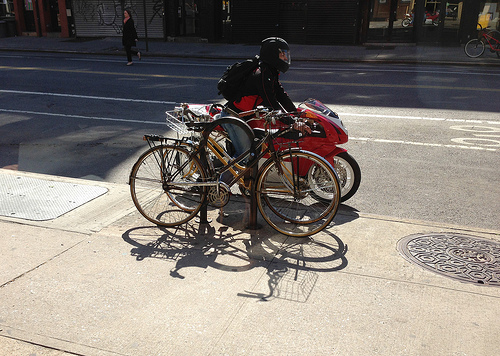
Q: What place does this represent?
A: It represents the city.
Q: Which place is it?
A: It is a city.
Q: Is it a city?
A: Yes, it is a city.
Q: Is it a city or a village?
A: It is a city.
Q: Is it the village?
A: No, it is the city.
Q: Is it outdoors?
A: Yes, it is outdoors.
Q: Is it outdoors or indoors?
A: It is outdoors.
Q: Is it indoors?
A: No, it is outdoors.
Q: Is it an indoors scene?
A: No, it is outdoors.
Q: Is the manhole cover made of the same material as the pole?
A: Yes, both the manhole cover and the pole are made of metal.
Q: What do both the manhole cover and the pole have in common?
A: The material, both the manhole cover and the pole are metallic.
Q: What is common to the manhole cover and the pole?
A: The material, both the manhole cover and the pole are metallic.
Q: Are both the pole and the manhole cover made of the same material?
A: Yes, both the pole and the manhole cover are made of metal.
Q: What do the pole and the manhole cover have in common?
A: The material, both the pole and the manhole cover are metallic.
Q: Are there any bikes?
A: Yes, there is a bike.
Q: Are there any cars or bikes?
A: Yes, there is a bike.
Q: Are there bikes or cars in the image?
A: Yes, there is a bike.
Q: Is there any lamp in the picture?
A: No, there are no lamps.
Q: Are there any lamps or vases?
A: No, there are no lamps or vases.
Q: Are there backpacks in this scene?
A: Yes, there is a backpack.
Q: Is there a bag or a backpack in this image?
A: Yes, there is a backpack.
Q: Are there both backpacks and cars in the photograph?
A: No, there is a backpack but no cars.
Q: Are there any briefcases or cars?
A: No, there are no cars or briefcases.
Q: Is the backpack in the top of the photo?
A: Yes, the backpack is in the top of the image.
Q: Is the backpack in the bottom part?
A: No, the backpack is in the top of the image.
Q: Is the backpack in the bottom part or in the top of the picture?
A: The backpack is in the top of the image.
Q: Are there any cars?
A: No, there are no cars.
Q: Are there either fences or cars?
A: No, there are no cars or fences.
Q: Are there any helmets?
A: Yes, there is a helmet.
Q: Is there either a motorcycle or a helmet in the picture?
A: Yes, there is a helmet.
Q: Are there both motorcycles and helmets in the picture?
A: Yes, there are both a helmet and a motorcycle.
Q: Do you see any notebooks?
A: No, there are no notebooks.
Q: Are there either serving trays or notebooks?
A: No, there are no notebooks or serving trays.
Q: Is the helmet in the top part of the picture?
A: Yes, the helmet is in the top of the image.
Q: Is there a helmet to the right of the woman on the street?
A: Yes, there is a helmet to the right of the woman.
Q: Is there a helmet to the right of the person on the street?
A: Yes, there is a helmet to the right of the woman.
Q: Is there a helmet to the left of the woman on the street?
A: No, the helmet is to the right of the woman.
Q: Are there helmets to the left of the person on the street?
A: No, the helmet is to the right of the woman.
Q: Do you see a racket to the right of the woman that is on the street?
A: No, there is a helmet to the right of the woman.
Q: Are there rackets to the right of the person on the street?
A: No, there is a helmet to the right of the woman.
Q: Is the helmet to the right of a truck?
A: No, the helmet is to the right of the woman.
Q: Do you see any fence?
A: No, there are no fences.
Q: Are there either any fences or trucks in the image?
A: No, there are no fences or trucks.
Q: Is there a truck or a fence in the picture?
A: No, there are no fences or trucks.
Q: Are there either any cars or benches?
A: No, there are no cars or benches.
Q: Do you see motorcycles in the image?
A: Yes, there is a motorcycle.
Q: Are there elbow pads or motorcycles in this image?
A: Yes, there is a motorcycle.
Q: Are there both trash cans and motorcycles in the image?
A: No, there is a motorcycle but no trash cans.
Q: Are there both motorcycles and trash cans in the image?
A: No, there is a motorcycle but no trash cans.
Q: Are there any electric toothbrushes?
A: No, there are no electric toothbrushes.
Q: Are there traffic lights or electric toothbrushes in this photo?
A: No, there are no electric toothbrushes or traffic lights.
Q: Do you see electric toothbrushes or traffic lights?
A: No, there are no electric toothbrushes or traffic lights.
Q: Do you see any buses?
A: No, there are no buses.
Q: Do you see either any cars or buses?
A: No, there are no buses or cars.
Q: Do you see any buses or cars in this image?
A: No, there are no buses or cars.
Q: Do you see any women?
A: Yes, there is a woman.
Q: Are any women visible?
A: Yes, there is a woman.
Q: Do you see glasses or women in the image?
A: Yes, there is a woman.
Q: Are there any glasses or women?
A: Yes, there is a woman.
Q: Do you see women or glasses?
A: Yes, there is a woman.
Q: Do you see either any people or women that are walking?
A: Yes, the woman is walking.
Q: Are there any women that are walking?
A: Yes, there is a woman that is walking.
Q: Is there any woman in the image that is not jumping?
A: Yes, there is a woman that is walking.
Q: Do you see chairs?
A: No, there are no chairs.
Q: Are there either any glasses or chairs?
A: No, there are no chairs or glasses.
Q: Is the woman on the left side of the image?
A: Yes, the woman is on the left of the image.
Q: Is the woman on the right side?
A: No, the woman is on the left of the image.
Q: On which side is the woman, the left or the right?
A: The woman is on the left of the image.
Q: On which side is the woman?
A: The woman is on the left of the image.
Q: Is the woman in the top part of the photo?
A: Yes, the woman is in the top of the image.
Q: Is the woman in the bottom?
A: No, the woman is in the top of the image.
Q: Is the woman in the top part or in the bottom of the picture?
A: The woman is in the top of the image.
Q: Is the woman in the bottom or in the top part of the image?
A: The woman is in the top of the image.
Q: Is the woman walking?
A: Yes, the woman is walking.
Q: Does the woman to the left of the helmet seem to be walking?
A: Yes, the woman is walking.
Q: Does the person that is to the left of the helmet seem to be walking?
A: Yes, the woman is walking.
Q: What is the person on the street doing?
A: The woman is walking.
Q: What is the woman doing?
A: The woman is walking.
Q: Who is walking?
A: The woman is walking.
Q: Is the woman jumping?
A: No, the woman is walking.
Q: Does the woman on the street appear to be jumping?
A: No, the woman is walking.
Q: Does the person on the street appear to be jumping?
A: No, the woman is walking.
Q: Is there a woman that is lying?
A: No, there is a woman but she is walking.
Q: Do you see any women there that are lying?
A: No, there is a woman but she is walking.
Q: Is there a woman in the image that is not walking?
A: No, there is a woman but she is walking.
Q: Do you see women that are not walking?
A: No, there is a woman but she is walking.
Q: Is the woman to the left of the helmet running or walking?
A: The woman is walking.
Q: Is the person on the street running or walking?
A: The woman is walking.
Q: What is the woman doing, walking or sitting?
A: The woman is walking.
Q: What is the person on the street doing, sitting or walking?
A: The woman is walking.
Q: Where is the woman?
A: The woman is on the street.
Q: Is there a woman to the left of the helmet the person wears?
A: Yes, there is a woman to the left of the helmet.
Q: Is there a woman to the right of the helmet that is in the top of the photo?
A: No, the woman is to the left of the helmet.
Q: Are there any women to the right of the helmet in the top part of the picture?
A: No, the woman is to the left of the helmet.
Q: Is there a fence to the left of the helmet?
A: No, there is a woman to the left of the helmet.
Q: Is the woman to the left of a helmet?
A: Yes, the woman is to the left of a helmet.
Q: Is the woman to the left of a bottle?
A: No, the woman is to the left of a helmet.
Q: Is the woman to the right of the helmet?
A: No, the woman is to the left of the helmet.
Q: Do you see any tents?
A: No, there are no tents.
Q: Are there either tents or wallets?
A: No, there are no tents or wallets.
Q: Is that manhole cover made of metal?
A: Yes, the manhole cover is made of metal.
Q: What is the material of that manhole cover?
A: The manhole cover is made of metal.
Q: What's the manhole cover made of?
A: The manhole cover is made of metal.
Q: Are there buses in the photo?
A: No, there are no buses.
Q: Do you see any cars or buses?
A: No, there are no buses or cars.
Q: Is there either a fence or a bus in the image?
A: No, there are no fences or buses.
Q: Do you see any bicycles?
A: Yes, there is a bicycle.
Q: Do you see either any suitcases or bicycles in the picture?
A: Yes, there is a bicycle.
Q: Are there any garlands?
A: No, there are no garlands.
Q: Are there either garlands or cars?
A: No, there are no garlands or cars.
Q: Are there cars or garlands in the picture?
A: No, there are no garlands or cars.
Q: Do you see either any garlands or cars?
A: No, there are no garlands or cars.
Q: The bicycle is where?
A: The bicycle is on the sidewalk.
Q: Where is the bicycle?
A: The bicycle is on the sidewalk.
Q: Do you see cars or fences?
A: No, there are no cars or fences.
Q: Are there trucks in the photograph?
A: No, there are no trucks.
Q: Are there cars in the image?
A: No, there are no cars.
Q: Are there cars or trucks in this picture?
A: No, there are no cars or trucks.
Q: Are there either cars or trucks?
A: No, there are no cars or trucks.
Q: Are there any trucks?
A: No, there are no trucks.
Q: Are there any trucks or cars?
A: No, there are no trucks or cars.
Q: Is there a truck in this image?
A: No, there are no trucks.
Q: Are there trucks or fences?
A: No, there are no trucks or fences.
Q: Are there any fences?
A: No, there are no fences.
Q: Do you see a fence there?
A: No, there are no fences.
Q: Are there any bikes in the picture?
A: Yes, there are bikes.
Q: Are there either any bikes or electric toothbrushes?
A: Yes, there are bikes.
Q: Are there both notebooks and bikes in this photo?
A: No, there are bikes but no notebooks.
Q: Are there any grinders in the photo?
A: No, there are no grinders.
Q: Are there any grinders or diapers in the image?
A: No, there are no grinders or diapers.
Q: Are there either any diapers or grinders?
A: No, there are no grinders or diapers.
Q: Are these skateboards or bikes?
A: These are bikes.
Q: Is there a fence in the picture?
A: No, there are no fences.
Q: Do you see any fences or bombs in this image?
A: No, there are no fences or bombs.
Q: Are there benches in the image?
A: No, there are no benches.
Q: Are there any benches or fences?
A: No, there are no benches or fences.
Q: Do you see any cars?
A: No, there are no cars.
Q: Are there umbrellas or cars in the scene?
A: No, there are no cars or umbrellas.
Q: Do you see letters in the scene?
A: Yes, there are letters.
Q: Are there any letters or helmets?
A: Yes, there are letters.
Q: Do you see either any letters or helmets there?
A: Yes, there are letters.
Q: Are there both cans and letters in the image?
A: No, there are letters but no cans.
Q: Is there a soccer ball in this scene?
A: No, there are no soccer balls.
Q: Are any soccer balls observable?
A: No, there are no soccer balls.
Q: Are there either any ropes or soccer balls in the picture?
A: No, there are no soccer balls or ropes.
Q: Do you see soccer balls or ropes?
A: No, there are no soccer balls or ropes.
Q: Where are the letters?
A: The letters are on the street.